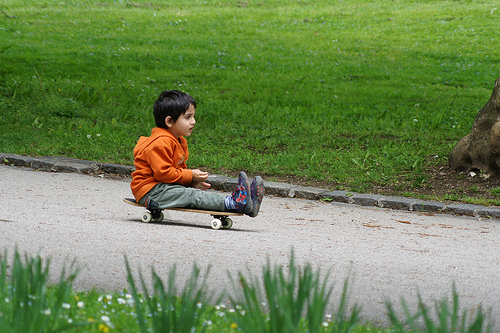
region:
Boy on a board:
[121, 83, 277, 235]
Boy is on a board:
[118, 83, 270, 232]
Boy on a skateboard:
[121, 85, 268, 233]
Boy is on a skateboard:
[116, 90, 276, 234]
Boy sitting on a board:
[118, 86, 273, 233]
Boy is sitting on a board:
[117, 82, 275, 234]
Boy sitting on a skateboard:
[112, 86, 273, 238]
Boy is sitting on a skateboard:
[115, 76, 278, 231]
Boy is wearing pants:
[139, 179, 236, 218]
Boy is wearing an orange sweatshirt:
[125, 123, 199, 197]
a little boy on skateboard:
[118, 60, 275, 245]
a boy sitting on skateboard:
[116, 76, 286, 240]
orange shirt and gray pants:
[116, 112, 247, 220]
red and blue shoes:
[227, 164, 269, 224]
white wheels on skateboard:
[133, 207, 248, 241]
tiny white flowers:
[38, 285, 223, 332]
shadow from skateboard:
[110, 208, 275, 243]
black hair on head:
[138, 71, 200, 136]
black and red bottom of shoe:
[248, 178, 267, 223]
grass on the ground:
[8, 7, 490, 176]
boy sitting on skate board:
[122, 90, 272, 239]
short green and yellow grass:
[294, 52, 354, 114]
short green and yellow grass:
[311, 138, 356, 176]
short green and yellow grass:
[430, 65, 471, 107]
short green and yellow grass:
[355, 75, 394, 110]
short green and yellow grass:
[277, 52, 307, 84]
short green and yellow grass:
[89, 30, 110, 50]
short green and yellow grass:
[24, 52, 69, 85]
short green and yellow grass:
[314, 75, 351, 96]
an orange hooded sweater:
[130, 127, 188, 197]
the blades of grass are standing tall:
[0, 250, 482, 330]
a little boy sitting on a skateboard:
[125, 90, 262, 230]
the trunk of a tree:
[446, 90, 496, 170]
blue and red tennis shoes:
[227, 170, 263, 211]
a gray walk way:
[0, 160, 495, 310]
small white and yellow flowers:
[67, 290, 127, 330]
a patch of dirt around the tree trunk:
[372, 160, 491, 199]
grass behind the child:
[11, 6, 455, 164]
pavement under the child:
[21, 166, 492, 323]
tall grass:
[13, 252, 369, 327]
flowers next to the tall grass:
[50, 285, 200, 330]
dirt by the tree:
[410, 138, 482, 198]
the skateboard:
[122, 191, 257, 226]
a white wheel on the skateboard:
[207, 218, 224, 226]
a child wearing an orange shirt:
[121, 90, 267, 222]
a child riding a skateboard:
[118, 90, 263, 221]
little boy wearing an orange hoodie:
[123, 88, 265, 233]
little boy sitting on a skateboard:
[121, 88, 266, 230]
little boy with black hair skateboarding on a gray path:
[123, 89, 265, 230]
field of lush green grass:
[0, 0, 496, 205]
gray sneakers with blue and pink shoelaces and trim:
[230, 169, 265, 216]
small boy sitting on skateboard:
[119, 82, 269, 234]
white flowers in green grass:
[160, 6, 272, 75]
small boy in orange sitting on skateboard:
[114, 84, 269, 233]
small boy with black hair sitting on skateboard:
[117, 83, 269, 230]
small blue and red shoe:
[227, 170, 252, 215]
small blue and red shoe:
[246, 170, 271, 216]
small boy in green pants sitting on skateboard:
[115, 88, 267, 236]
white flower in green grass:
[410, 110, 424, 130]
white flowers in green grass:
[434, 23, 484, 52]